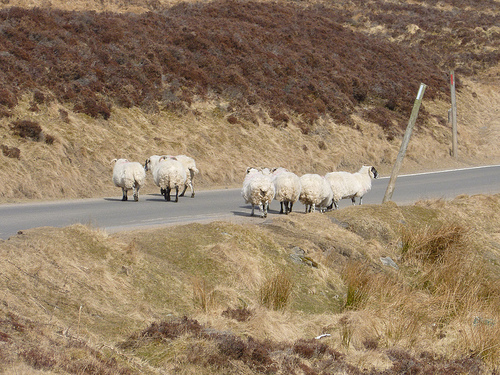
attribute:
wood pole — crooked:
[382, 78, 431, 206]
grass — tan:
[2, 72, 494, 201]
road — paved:
[0, 159, 500, 245]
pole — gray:
[381, 69, 452, 171]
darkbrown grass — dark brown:
[9, 10, 428, 95]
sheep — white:
[240, 163, 379, 219]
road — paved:
[0, 166, 500, 239]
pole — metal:
[443, 65, 462, 167]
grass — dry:
[2, 6, 493, 189]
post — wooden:
[446, 70, 458, 159]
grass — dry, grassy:
[111, 244, 357, 346]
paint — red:
[445, 72, 455, 87]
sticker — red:
[447, 74, 456, 89]